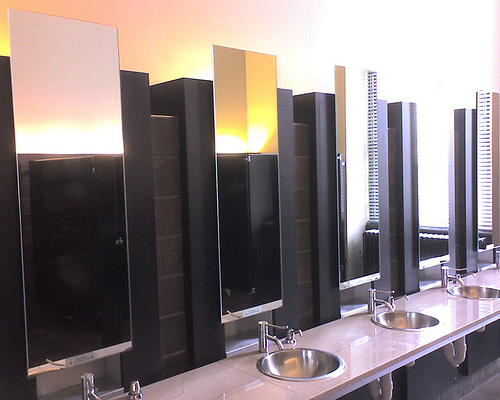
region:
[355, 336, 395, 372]
Shiny white sink counter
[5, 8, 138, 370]
A long wall mirror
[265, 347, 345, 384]
A round stainless steel sink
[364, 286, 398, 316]
A stainless steel bathroom faucet fixture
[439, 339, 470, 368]
White PVC pipe under sink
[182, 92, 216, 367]
A black wall next to mirror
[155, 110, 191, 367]
A black tiled wall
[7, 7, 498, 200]
Top of five mirrors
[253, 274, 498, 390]
Three stainless steel sinks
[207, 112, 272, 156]
The light reflection in the mirror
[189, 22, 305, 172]
yellow lighting effect reflected in mirror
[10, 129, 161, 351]
bathroom stall door reflected in mirror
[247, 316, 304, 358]
silver water spigot in bathroom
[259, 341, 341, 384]
silver colored sink in bathroom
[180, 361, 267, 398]
granite counter top in bathroom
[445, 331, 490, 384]
white PVC pipes under bathroom sink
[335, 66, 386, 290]
reflection of window in bathroom mirror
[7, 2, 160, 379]
bathroom wall mirror over sink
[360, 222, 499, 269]
reflection of radiator in bathroom mirror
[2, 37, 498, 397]
bathroom sink area with marge wall mirrors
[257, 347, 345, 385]
a silver sink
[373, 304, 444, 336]
a silver sink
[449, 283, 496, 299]
a silver sink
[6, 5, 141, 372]
a nice huge mirror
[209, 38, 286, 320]
a nice huge mirror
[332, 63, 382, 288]
a nice huge mirror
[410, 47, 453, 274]
a nice huge mirror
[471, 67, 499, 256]
a nice huge mirror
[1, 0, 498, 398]
a bathroom scene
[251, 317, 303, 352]
a tap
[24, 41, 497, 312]
Five mirrors on wall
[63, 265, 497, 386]
Four silver sinks in countertop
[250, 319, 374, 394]
Silver bowl shaped sink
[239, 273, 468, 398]
Two bowl shaped sinks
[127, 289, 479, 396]
White countertop in bathroom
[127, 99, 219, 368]
Black panels on wall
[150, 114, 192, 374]
Brown bricks on wall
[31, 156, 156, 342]
Bathroom stall reflection in mirror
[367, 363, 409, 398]
Pipe under sink counter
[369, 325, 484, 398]
two white pipes under counter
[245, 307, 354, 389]
a silver bathroom sink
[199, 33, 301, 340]
a bathroom mirror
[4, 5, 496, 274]
five bathroom mirrors in a row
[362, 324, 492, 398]
two sets of pipe under the sink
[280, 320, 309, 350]
a silver soap dispenser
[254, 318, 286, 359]
a silver water faucet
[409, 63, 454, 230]
the sunlight reflected in a mirror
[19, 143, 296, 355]
bathroom stall reflected in the mirrors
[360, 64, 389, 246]
a reflection of window blinds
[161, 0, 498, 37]
a white bathroom wall